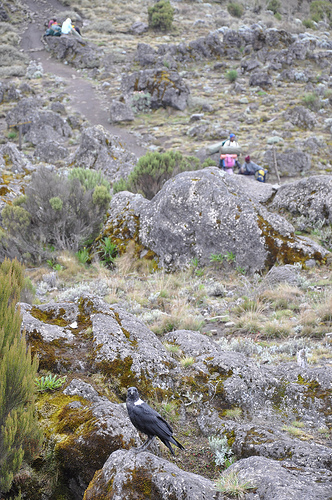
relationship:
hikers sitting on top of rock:
[215, 143, 281, 185] [166, 165, 261, 244]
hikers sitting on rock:
[215, 143, 281, 185] [166, 165, 261, 244]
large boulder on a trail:
[28, 161, 116, 240] [88, 110, 141, 152]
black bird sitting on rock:
[110, 386, 187, 456] [84, 446, 193, 499]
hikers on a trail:
[215, 143, 281, 185] [88, 110, 141, 152]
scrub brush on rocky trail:
[130, 145, 179, 181] [88, 110, 141, 152]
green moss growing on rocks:
[245, 223, 287, 263] [227, 206, 293, 254]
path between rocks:
[66, 67, 101, 100] [108, 82, 166, 108]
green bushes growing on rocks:
[69, 175, 109, 207] [227, 206, 293, 254]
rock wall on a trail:
[49, 78, 159, 138] [88, 110, 141, 152]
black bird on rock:
[110, 386, 187, 456] [84, 446, 193, 499]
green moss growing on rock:
[245, 223, 287, 263] [166, 165, 261, 244]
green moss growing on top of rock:
[245, 223, 287, 263] [166, 165, 261, 244]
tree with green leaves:
[141, 8, 183, 29] [151, 3, 176, 17]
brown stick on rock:
[272, 146, 291, 186] [260, 146, 294, 161]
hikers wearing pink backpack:
[217, 133, 239, 173] [218, 152, 238, 167]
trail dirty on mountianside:
[88, 110, 141, 152] [17, 9, 207, 101]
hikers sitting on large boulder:
[215, 143, 281, 185] [28, 161, 116, 240]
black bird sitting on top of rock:
[110, 386, 187, 456] [84, 446, 193, 499]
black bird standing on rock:
[110, 386, 187, 456] [84, 446, 193, 499]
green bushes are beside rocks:
[69, 175, 109, 207] [227, 206, 293, 254]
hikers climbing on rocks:
[215, 143, 281, 185] [227, 206, 293, 254]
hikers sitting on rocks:
[215, 143, 281, 185] [227, 206, 293, 254]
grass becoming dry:
[59, 290, 136, 345] [94, 290, 162, 343]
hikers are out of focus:
[215, 143, 281, 185] [210, 121, 263, 146]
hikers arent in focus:
[215, 143, 281, 185] [210, 121, 263, 146]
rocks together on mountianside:
[227, 206, 293, 254] [17, 9, 207, 101]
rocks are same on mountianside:
[227, 206, 293, 254] [17, 9, 207, 101]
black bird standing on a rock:
[110, 386, 187, 456] [84, 446, 193, 499]